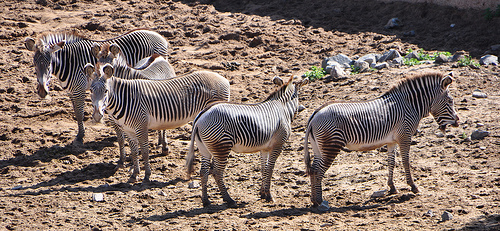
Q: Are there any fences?
A: No, there are no fences.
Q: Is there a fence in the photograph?
A: No, there are no fences.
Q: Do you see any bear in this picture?
A: No, there are no bears.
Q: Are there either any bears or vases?
A: No, there are no bears or vases.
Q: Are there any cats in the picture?
A: No, there are no cats.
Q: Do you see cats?
A: No, there are no cats.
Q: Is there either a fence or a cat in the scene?
A: No, there are no cats or fences.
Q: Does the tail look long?
A: Yes, the tail is long.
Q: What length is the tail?
A: The tail is long.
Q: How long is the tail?
A: The tail is long.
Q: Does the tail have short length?
A: No, the tail is long.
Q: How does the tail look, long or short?
A: The tail is long.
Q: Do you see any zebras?
A: Yes, there is a zebra.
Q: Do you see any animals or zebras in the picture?
A: Yes, there is a zebra.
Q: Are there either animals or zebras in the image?
A: Yes, there is a zebra.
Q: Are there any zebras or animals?
A: Yes, there is a zebra.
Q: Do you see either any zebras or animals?
A: Yes, there is a zebra.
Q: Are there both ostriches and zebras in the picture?
A: No, there is a zebra but no ostriches.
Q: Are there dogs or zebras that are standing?
A: Yes, the zebra is standing.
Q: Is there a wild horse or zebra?
A: Yes, there is a wild zebra.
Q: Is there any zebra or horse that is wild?
A: Yes, the zebra is wild.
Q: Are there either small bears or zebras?
A: Yes, there is a small zebra.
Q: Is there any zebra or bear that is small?
A: Yes, the zebra is small.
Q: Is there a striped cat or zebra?
A: Yes, there is a striped zebra.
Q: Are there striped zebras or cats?
A: Yes, there is a striped zebra.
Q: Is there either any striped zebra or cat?
A: Yes, there is a striped zebra.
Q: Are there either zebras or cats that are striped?
A: Yes, the zebra is striped.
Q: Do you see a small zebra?
A: Yes, there is a small zebra.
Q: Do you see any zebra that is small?
A: Yes, there is a zebra that is small.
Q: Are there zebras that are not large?
A: Yes, there is a small zebra.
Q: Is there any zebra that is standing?
A: Yes, there is a zebra that is standing.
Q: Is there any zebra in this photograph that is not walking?
A: Yes, there is a zebra that is standing.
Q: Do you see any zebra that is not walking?
A: Yes, there is a zebra that is standing .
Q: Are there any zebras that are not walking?
A: Yes, there is a zebra that is standing.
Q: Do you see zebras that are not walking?
A: Yes, there is a zebra that is standing .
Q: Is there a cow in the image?
A: No, there are no cows.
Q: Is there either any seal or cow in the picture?
A: No, there are no cows or seals.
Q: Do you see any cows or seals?
A: No, there are no cows or seals.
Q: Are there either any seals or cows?
A: No, there are no cows or seals.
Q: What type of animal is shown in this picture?
A: The animal is a zebra.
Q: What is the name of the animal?
A: The animal is a zebra.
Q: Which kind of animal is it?
A: The animal is a zebra.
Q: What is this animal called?
A: This is a zebra.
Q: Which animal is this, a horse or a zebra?
A: This is a zebra.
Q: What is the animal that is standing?
A: The animal is a zebra.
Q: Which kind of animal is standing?
A: The animal is a zebra.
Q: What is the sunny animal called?
A: The animal is a zebra.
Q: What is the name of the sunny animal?
A: The animal is a zebra.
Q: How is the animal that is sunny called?
A: The animal is a zebra.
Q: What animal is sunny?
A: The animal is a zebra.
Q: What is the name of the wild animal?
A: The animal is a zebra.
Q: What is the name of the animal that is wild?
A: The animal is a zebra.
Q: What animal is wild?
A: The animal is a zebra.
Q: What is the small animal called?
A: The animal is a zebra.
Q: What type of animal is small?
A: The animal is a zebra.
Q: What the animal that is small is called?
A: The animal is a zebra.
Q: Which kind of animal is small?
A: The animal is a zebra.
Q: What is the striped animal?
A: The animal is a zebra.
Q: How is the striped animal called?
A: The animal is a zebra.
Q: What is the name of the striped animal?
A: The animal is a zebra.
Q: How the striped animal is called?
A: The animal is a zebra.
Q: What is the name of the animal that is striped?
A: The animal is a zebra.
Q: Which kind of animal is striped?
A: The animal is a zebra.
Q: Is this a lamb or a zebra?
A: This is a zebra.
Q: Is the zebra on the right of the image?
A: Yes, the zebra is on the right of the image.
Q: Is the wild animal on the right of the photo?
A: Yes, the zebra is on the right of the image.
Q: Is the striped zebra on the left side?
A: No, the zebra is on the right of the image.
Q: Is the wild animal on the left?
A: No, the zebra is on the right of the image.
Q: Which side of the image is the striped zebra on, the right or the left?
A: The zebra is on the right of the image.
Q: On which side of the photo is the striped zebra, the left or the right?
A: The zebra is on the right of the image.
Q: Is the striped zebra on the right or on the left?
A: The zebra is on the right of the image.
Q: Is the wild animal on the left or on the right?
A: The zebra is on the right of the image.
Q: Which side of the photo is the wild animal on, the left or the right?
A: The zebra is on the right of the image.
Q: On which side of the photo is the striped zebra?
A: The zebra is on the right of the image.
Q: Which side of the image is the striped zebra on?
A: The zebra is on the right of the image.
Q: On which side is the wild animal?
A: The zebra is on the right of the image.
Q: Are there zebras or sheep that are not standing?
A: No, there is a zebra but it is standing.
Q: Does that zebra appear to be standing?
A: Yes, the zebra is standing.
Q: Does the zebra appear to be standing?
A: Yes, the zebra is standing.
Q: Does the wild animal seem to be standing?
A: Yes, the zebra is standing.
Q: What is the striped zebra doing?
A: The zebra is standing.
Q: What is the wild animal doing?
A: The zebra is standing.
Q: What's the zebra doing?
A: The zebra is standing.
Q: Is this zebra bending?
A: No, the zebra is standing.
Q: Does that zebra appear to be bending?
A: No, the zebra is standing.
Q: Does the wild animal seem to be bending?
A: No, the zebra is standing.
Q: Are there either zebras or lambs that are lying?
A: No, there is a zebra but it is standing.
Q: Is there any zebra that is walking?
A: No, there is a zebra but it is standing.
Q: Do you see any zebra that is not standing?
A: No, there is a zebra but it is standing.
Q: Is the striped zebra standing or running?
A: The zebra is standing.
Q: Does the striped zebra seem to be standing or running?
A: The zebra is standing.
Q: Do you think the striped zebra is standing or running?
A: The zebra is standing.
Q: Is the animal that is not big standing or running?
A: The zebra is standing.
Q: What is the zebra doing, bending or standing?
A: The zebra is standing.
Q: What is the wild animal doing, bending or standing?
A: The zebra is standing.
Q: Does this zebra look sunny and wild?
A: Yes, the zebra is sunny and wild.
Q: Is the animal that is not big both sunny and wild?
A: Yes, the zebra is sunny and wild.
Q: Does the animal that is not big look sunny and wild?
A: Yes, the zebra is sunny and wild.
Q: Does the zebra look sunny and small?
A: Yes, the zebra is sunny and small.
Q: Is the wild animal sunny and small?
A: Yes, the zebra is sunny and small.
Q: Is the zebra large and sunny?
A: No, the zebra is sunny but small.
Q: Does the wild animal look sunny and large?
A: No, the zebra is sunny but small.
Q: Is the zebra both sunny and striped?
A: Yes, the zebra is sunny and striped.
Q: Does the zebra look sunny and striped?
A: Yes, the zebra is sunny and striped.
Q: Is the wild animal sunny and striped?
A: Yes, the zebra is sunny and striped.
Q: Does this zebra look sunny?
A: Yes, the zebra is sunny.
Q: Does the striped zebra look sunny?
A: Yes, the zebra is sunny.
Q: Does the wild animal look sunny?
A: Yes, the zebra is sunny.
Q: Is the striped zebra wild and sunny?
A: Yes, the zebra is wild and sunny.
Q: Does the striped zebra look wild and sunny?
A: Yes, the zebra is wild and sunny.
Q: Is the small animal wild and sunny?
A: Yes, the zebra is wild and sunny.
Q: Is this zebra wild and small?
A: Yes, the zebra is wild and small.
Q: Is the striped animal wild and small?
A: Yes, the zebra is wild and small.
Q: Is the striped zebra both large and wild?
A: No, the zebra is wild but small.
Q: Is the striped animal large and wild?
A: No, the zebra is wild but small.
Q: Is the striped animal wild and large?
A: No, the zebra is wild but small.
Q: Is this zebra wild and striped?
A: Yes, the zebra is wild and striped.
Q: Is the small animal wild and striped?
A: Yes, the zebra is wild and striped.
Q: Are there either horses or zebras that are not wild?
A: No, there is a zebra but it is wild.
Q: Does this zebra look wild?
A: Yes, the zebra is wild.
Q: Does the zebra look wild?
A: Yes, the zebra is wild.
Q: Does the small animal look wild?
A: Yes, the zebra is wild.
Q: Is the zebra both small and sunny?
A: Yes, the zebra is small and sunny.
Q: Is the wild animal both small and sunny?
A: Yes, the zebra is small and sunny.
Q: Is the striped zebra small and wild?
A: Yes, the zebra is small and wild.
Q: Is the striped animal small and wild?
A: Yes, the zebra is small and wild.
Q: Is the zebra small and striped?
A: Yes, the zebra is small and striped.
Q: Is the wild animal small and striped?
A: Yes, the zebra is small and striped.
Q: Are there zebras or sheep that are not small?
A: No, there is a zebra but it is small.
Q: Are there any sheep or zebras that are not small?
A: No, there is a zebra but it is small.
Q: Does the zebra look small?
A: Yes, the zebra is small.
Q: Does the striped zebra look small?
A: Yes, the zebra is small.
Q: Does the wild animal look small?
A: Yes, the zebra is small.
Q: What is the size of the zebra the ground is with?
A: The zebra is small.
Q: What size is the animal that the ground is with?
A: The zebra is small.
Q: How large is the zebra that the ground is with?
A: The zebra is small.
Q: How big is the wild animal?
A: The zebra is small.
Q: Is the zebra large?
A: No, the zebra is small.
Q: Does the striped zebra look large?
A: No, the zebra is small.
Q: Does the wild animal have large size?
A: No, the zebra is small.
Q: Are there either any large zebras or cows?
A: No, there is a zebra but it is small.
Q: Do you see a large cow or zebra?
A: No, there is a zebra but it is small.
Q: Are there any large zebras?
A: No, there is a zebra but it is small.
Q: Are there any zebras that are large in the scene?
A: No, there is a zebra but it is small.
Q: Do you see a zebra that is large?
A: No, there is a zebra but it is small.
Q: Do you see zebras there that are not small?
A: No, there is a zebra but it is small.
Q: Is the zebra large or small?
A: The zebra is small.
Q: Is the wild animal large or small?
A: The zebra is small.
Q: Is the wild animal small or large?
A: The zebra is small.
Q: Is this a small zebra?
A: Yes, this is a small zebra.